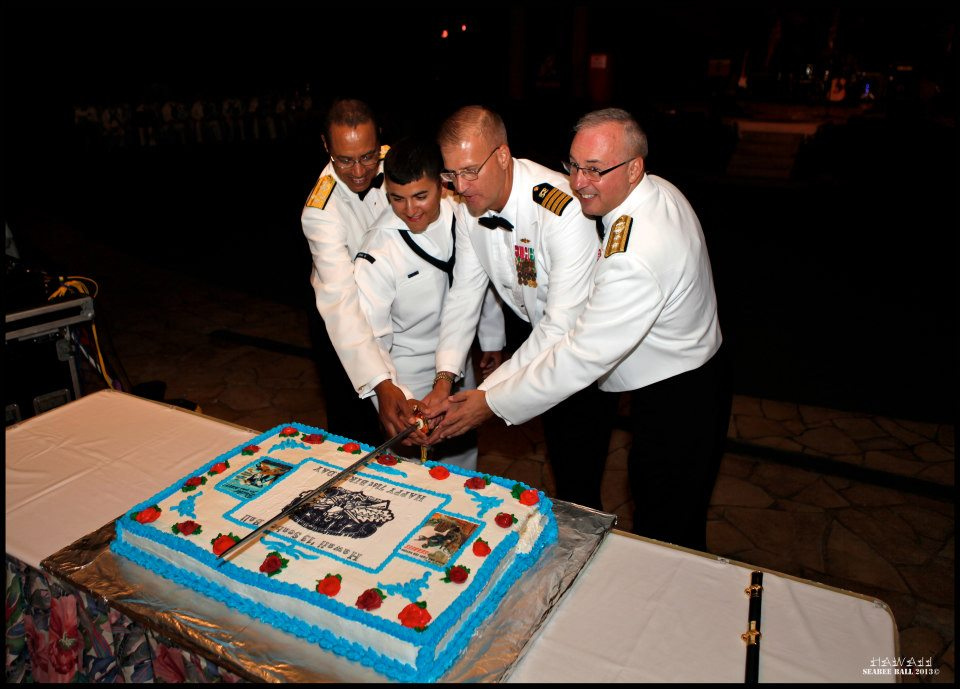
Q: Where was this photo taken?
A: At a celebration.